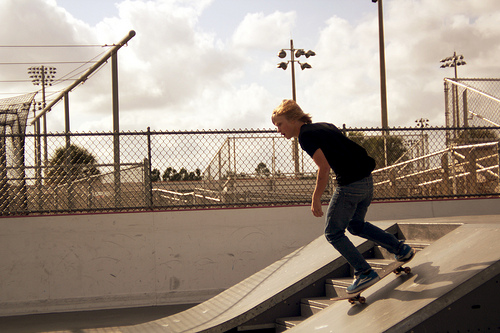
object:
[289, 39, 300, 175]
pole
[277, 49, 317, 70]
light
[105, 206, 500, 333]
cement ramp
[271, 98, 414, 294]
boy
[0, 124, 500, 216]
railings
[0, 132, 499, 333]
park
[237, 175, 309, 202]
area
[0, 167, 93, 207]
area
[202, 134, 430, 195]
fence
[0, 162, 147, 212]
fence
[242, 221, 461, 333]
stairs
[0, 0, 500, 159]
clouds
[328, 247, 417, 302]
wood slat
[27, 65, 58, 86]
lighting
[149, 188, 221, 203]
metal handrail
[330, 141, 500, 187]
metal handrail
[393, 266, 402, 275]
wheel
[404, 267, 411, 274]
wheel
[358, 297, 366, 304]
wheel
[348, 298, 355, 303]
wheel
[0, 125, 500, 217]
fence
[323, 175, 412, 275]
jeans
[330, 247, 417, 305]
skateboard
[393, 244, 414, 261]
shoe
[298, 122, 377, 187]
shirt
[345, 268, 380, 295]
shoe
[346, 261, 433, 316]
shadow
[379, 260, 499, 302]
shadow